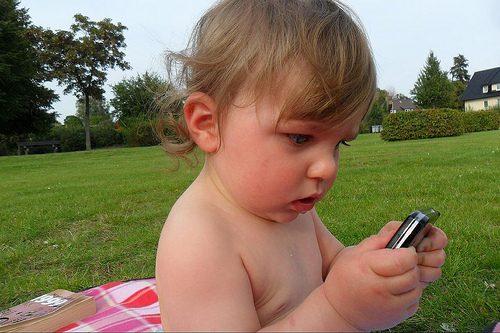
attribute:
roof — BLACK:
[457, 65, 497, 97]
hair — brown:
[197, 19, 329, 74]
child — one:
[164, 16, 444, 321]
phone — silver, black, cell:
[376, 200, 442, 257]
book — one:
[13, 286, 100, 330]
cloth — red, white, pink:
[46, 276, 179, 332]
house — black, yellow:
[461, 58, 498, 126]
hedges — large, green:
[377, 98, 498, 152]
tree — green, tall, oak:
[43, 11, 131, 149]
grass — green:
[11, 160, 133, 204]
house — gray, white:
[382, 90, 420, 121]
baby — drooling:
[188, 8, 368, 234]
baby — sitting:
[140, 13, 441, 318]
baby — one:
[183, 13, 420, 319]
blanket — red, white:
[1, 238, 207, 330]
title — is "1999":
[0, 278, 98, 319]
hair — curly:
[146, 0, 393, 170]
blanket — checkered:
[0, 253, 189, 330]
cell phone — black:
[343, 189, 498, 305]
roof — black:
[439, 49, 499, 139]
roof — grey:
[373, 70, 442, 140]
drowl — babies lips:
[295, 201, 318, 221]